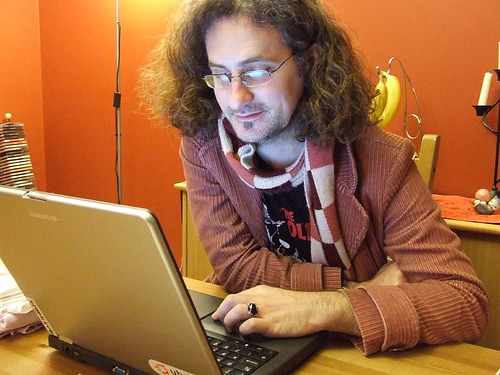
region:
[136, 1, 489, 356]
Man sitting at desk in front of computer.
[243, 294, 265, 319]
Man wearing ring on left hand finger.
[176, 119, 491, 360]
Man dressed in brown corduroy jacket.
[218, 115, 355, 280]
Man wearing white, pink and maroon wool scarf around neck.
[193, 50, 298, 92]
Man wearing eyeglasses over eyes.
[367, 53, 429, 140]
Bananas hanging on ripening rack.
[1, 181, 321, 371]
Laptop computer sitting on desk.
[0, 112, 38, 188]
Stack of disks on side of man near wall.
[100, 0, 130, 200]
Lamp pole next to disks near wall.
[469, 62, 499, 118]
Leaning candle in candle holder behind man.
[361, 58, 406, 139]
Yellow bananas hanging up on rock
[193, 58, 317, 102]
Black framed glasses on face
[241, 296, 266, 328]
Black ring on finger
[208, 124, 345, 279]
Red and white scarf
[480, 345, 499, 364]
Light brown wood grain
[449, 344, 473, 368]
Light brown wood grain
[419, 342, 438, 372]
Light brown wood grain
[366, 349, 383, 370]
Light brown wood grain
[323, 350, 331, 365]
Light brown wood grain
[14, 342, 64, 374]
Light brown wood grain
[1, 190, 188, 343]
a laptop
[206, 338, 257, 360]
a keyboard on the laptop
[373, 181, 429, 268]
man wearing a jacket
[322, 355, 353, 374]
a table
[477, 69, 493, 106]
a white candle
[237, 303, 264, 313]
man is wearing a ring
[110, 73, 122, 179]
a cord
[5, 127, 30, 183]
cds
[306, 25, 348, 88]
man has long hair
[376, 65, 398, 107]
yellow bananas hanging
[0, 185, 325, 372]
an open laptop computer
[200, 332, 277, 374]
a black computer keyboard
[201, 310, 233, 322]
a computer track pad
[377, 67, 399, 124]
a yellow ripe banana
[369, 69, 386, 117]
a yellow ripe banana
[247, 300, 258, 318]
a men's black ring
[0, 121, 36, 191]
a stack of CDs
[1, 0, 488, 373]
a man sitting at computer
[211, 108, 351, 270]
a red and white scarf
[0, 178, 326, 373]
open silver and black laptop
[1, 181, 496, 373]
open silver and black laptop on wooden desk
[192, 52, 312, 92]
pair of eye glasses on man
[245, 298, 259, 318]
ring with black stone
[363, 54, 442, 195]
bunch of bananas hanging from metal rack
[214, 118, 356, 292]
red and white checkers scarf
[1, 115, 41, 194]
stack of compact discs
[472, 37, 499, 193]
black metal candelabra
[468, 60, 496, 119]
white candle in black candelabra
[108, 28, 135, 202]
string of wires attached to wall vertically